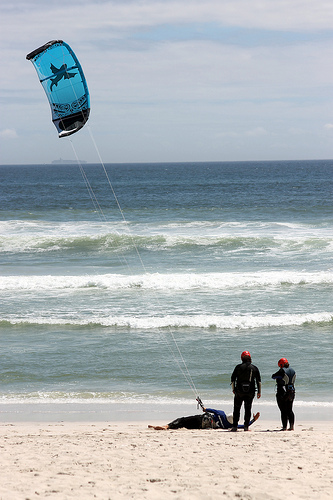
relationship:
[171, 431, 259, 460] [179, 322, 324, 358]
sand in ocean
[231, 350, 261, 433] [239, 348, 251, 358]
man in helmet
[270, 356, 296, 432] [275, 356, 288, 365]
people in helmet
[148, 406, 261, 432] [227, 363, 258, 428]
man in wet suits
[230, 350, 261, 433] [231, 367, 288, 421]
man in suits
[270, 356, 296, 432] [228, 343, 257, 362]
people wearing helmet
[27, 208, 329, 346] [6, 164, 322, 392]
waves on ocean water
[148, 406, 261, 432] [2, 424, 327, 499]
man in sand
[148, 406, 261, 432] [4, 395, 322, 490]
man laying on beach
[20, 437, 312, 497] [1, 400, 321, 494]
tracks on beach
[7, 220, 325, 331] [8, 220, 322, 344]
foam on waves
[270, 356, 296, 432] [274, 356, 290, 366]
people wearing helmet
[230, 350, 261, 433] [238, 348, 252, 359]
man wearing helmet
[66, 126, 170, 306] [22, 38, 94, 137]
lines attached to kite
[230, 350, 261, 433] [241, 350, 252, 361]
man wear helmet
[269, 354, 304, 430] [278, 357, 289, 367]
people wear helmet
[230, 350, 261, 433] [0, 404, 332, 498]
man on beach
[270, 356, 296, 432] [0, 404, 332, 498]
people on beach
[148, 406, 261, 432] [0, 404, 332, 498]
man on beach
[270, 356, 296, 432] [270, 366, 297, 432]
people wearing wet suit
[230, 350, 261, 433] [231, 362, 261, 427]
man wearing suits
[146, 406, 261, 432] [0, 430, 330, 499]
man lying on beach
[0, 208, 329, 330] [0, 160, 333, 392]
waves on ocean water